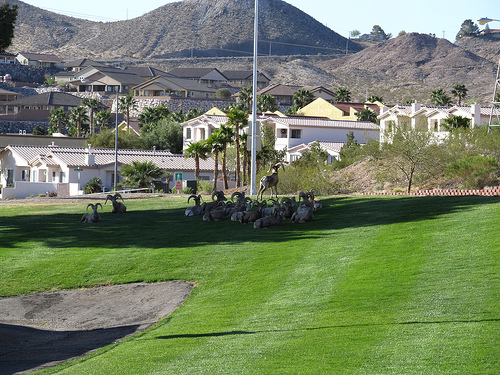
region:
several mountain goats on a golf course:
[80, 163, 322, 230]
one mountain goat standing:
[261, 162, 286, 194]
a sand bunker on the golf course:
[2, 280, 186, 372]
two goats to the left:
[77, 192, 128, 224]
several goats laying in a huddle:
[184, 188, 319, 230]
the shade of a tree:
[10, 192, 485, 243]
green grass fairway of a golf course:
[9, 199, 489, 373]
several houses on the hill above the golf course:
[8, 53, 498, 201]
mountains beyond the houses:
[3, 1, 495, 103]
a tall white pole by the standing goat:
[248, 1, 261, 196]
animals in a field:
[155, 154, 390, 296]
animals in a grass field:
[168, 167, 489, 312]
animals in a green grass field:
[184, 151, 356, 243]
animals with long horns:
[173, 159, 460, 301]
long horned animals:
[169, 129, 394, 248]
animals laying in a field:
[161, 143, 310, 208]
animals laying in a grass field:
[193, 143, 439, 279]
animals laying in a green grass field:
[179, 144, 392, 254]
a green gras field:
[228, 247, 480, 372]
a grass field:
[267, 241, 424, 371]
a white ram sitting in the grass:
[79, 201, 104, 222]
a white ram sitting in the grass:
[104, 191, 126, 211]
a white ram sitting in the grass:
[181, 193, 202, 220]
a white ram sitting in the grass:
[200, 191, 225, 211]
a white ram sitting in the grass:
[201, 200, 229, 220]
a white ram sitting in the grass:
[231, 202, 256, 223]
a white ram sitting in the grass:
[250, 205, 287, 230]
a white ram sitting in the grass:
[290, 201, 310, 223]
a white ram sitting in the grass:
[298, 189, 315, 205]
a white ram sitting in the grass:
[261, 197, 278, 209]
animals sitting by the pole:
[171, 188, 360, 229]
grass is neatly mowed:
[206, 231, 495, 374]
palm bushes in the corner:
[110, 146, 161, 203]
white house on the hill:
[373, 102, 499, 148]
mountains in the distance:
[26, 16, 252, 56]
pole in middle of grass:
[229, 1, 262, 201]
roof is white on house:
[9, 137, 200, 169]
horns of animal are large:
[68, 204, 129, 212]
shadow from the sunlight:
[168, 303, 490, 342]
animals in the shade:
[32, 198, 437, 242]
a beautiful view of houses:
[121, 53, 488, 186]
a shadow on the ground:
[28, 304, 140, 369]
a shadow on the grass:
[23, 301, 145, 372]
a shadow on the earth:
[20, 295, 175, 373]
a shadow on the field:
[4, 286, 129, 362]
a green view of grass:
[198, 248, 484, 373]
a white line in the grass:
[218, 251, 335, 362]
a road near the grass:
[8, 262, 195, 339]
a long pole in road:
[219, 16, 304, 218]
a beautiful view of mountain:
[8, 6, 425, 153]